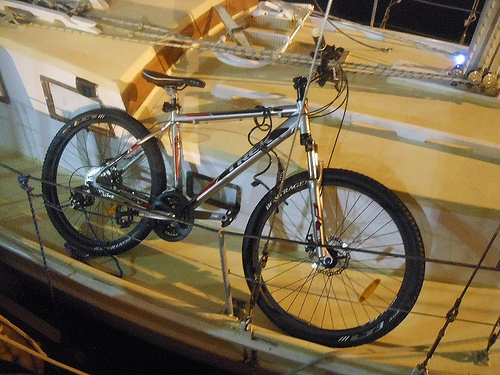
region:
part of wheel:
[376, 200, 430, 250]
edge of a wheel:
[254, 300, 271, 326]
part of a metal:
[292, 180, 328, 242]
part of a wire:
[466, 260, 479, 286]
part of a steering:
[297, 23, 344, 76]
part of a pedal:
[113, 209, 148, 235]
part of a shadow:
[450, 210, 477, 237]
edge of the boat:
[162, 297, 215, 364]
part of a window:
[426, 4, 460, 29]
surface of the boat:
[377, 325, 409, 361]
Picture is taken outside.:
[40, 7, 482, 342]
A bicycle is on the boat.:
[49, 62, 436, 309]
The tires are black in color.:
[37, 106, 167, 249]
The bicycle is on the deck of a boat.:
[44, 47, 446, 304]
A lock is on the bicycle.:
[244, 86, 309, 236]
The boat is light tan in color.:
[82, 61, 476, 177]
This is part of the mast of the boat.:
[447, 40, 493, 99]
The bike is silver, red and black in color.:
[79, 64, 305, 199]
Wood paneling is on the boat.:
[132, 8, 232, 94]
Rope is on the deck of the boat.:
[108, 8, 471, 90]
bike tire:
[230, 148, 447, 358]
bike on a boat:
[35, 2, 445, 354]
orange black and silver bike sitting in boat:
[37, 41, 452, 298]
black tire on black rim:
[222, 151, 447, 361]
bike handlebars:
[283, 18, 359, 125]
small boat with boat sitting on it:
[25, 22, 483, 298]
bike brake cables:
[272, 41, 364, 142]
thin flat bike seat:
[138, 52, 219, 102]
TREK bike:
[223, 105, 293, 211]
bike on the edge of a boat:
[40, 33, 468, 325]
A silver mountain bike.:
[40, 26, 425, 349]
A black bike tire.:
[238, 166, 425, 348]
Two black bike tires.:
[37, 105, 427, 347]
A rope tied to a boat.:
[2, 0, 498, 87]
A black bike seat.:
[139, 67, 205, 88]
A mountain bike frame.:
[83, 93, 332, 265]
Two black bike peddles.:
[111, 200, 238, 228]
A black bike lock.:
[247, 106, 289, 214]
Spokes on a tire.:
[53, 120, 152, 244]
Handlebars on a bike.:
[311, 25, 351, 87]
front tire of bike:
[238, 166, 448, 348]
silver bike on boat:
[33, 52, 478, 364]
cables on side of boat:
[420, 254, 495, 362]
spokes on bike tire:
[346, 219, 376, 306]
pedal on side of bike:
[100, 189, 177, 234]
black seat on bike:
[131, 62, 209, 94]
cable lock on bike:
[245, 100, 285, 191]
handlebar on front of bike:
[301, 24, 353, 82]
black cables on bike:
[309, 79, 353, 133]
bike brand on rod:
[222, 137, 277, 179]